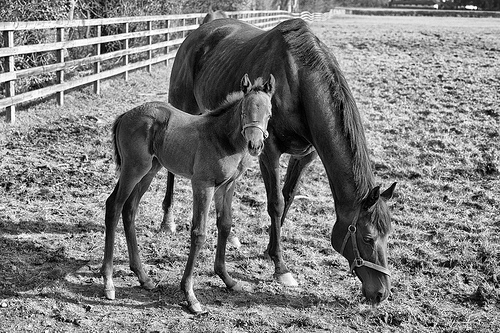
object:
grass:
[355, 27, 426, 121]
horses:
[102, 13, 424, 328]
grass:
[39, 139, 104, 203]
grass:
[8, 34, 498, 316]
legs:
[255, 146, 312, 296]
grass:
[93, 10, 408, 315]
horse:
[162, 15, 412, 305]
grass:
[424, 157, 468, 199]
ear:
[382, 181, 401, 204]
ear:
[363, 186, 382, 207]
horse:
[171, 6, 392, 303]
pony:
[110, 70, 307, 282]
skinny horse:
[101, 73, 276, 314]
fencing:
[5, 3, 287, 148]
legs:
[94, 154, 259, 315]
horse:
[177, 7, 420, 267]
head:
[234, 70, 283, 162]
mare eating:
[200, 120, 497, 247]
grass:
[452, 52, 494, 132]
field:
[381, 27, 497, 310]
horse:
[102, 80, 297, 326]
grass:
[0, 15, 498, 332]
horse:
[169, 165, 214, 330]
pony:
[93, 70, 277, 319]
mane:
[278, 17, 395, 233]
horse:
[98, 70, 277, 312]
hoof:
[270, 269, 297, 289]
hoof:
[229, 280, 245, 290]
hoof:
[190, 301, 207, 316]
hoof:
[141, 279, 158, 291]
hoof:
[102, 286, 119, 301]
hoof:
[157, 222, 174, 231]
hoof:
[227, 238, 242, 250]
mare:
[159, 10, 400, 303]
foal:
[98, 72, 273, 322]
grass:
[407, 90, 499, 218]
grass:
[246, 260, 383, 325]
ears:
[235, 67, 288, 98]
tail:
[102, 130, 132, 172]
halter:
[238, 83, 268, 137]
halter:
[337, 192, 391, 277]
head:
[329, 198, 390, 303]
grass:
[366, 14, 462, 141]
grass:
[389, 57, 490, 187]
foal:
[56, 108, 252, 315]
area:
[42, 15, 497, 328]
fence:
[18, 3, 199, 92]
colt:
[101, 70, 282, 315]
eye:
[362, 230, 377, 249]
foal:
[66, 67, 313, 252]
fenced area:
[39, 7, 151, 103]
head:
[213, 83, 278, 143]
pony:
[104, 61, 319, 313]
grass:
[409, 213, 486, 304]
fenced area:
[1, 4, 496, 331]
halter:
[236, 100, 268, 140]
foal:
[88, 66, 280, 313]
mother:
[158, 2, 398, 303]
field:
[3, 18, 492, 330]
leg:
[214, 176, 241, 290]